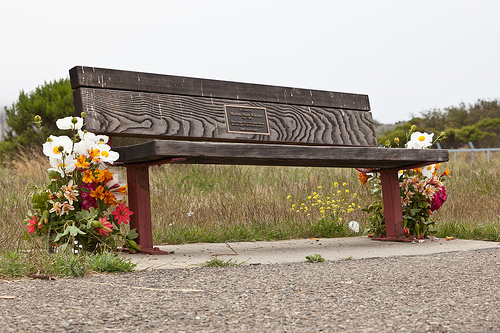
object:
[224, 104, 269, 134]
plaque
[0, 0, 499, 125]
sky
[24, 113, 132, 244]
flower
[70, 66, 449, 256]
bench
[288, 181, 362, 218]
flower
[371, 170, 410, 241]
leg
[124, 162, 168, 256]
leg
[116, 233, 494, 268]
pad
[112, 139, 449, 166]
seat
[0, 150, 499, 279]
grass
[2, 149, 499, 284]
field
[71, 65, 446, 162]
slat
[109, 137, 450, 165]
bench seat